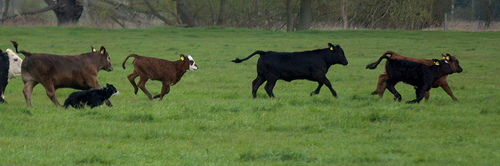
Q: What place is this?
A: It is a pasture.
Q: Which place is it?
A: It is a pasture.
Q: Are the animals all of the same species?
A: Yes, all the animals are cows.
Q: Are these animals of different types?
A: No, all the animals are cows.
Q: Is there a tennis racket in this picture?
A: No, there are no rackets.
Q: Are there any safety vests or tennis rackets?
A: No, there are no tennis rackets or safety vests.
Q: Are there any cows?
A: Yes, there is a cow.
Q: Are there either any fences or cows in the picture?
A: Yes, there is a cow.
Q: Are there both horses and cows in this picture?
A: No, there is a cow but no horses.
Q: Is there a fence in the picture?
A: No, there are no fences.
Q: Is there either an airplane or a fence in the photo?
A: No, there are no fences or airplanes.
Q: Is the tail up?
A: Yes, the tail is up.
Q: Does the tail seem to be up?
A: Yes, the tail is up.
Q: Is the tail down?
A: No, the tail is up.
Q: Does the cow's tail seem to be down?
A: No, the tail is up.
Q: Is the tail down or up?
A: The tail is up.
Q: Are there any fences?
A: No, there are no fences.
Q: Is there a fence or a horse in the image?
A: No, there are no fences or horses.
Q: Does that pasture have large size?
A: Yes, the pasture is large.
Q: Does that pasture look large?
A: Yes, the pasture is large.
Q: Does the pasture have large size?
A: Yes, the pasture is large.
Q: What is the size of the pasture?
A: The pasture is large.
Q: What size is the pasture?
A: The pasture is large.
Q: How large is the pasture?
A: The pasture is large.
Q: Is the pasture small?
A: No, the pasture is large.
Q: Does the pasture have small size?
A: No, the pasture is large.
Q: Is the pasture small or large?
A: The pasture is large.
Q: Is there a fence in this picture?
A: No, there are no fences.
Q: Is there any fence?
A: No, there are no fences.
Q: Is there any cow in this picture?
A: Yes, there is a cow.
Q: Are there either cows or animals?
A: Yes, there is a cow.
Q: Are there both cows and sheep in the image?
A: No, there is a cow but no sheep.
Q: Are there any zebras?
A: No, there are no zebras.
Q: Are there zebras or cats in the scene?
A: No, there are no zebras or cats.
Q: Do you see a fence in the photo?
A: No, there are no fences.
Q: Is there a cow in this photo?
A: Yes, there is a cow.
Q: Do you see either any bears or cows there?
A: Yes, there is a cow.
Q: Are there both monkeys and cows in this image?
A: No, there is a cow but no monkeys.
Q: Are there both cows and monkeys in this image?
A: No, there is a cow but no monkeys.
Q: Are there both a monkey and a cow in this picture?
A: No, there is a cow but no monkeys.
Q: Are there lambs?
A: No, there are no lambs.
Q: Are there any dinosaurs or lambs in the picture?
A: No, there are no lambs or dinosaurs.